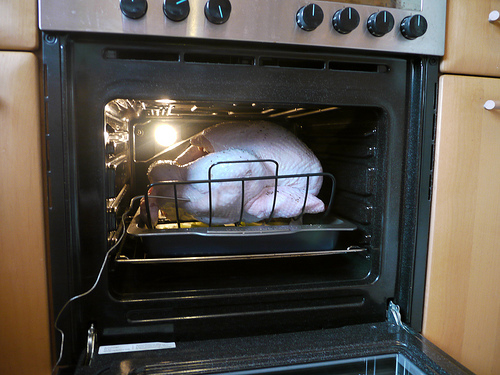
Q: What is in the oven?
A: A turkey.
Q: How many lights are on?
A: 1.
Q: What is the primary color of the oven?
A: Black.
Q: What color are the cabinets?
A: Brown.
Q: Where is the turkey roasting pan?
A: Oven.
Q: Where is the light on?
A: Oven.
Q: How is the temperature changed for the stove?
A: The controls.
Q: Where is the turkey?
A: Rack in pan.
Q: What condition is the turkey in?
A: Raw.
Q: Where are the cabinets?
A: Beside stove.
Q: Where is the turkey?
A: Oven.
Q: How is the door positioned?
A: Open.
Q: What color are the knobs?
A: Black.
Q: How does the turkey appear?
A: Uncooked.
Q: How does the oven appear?
A: Opened.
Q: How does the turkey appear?
A: Raw.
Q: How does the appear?
A: Opened.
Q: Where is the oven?
A: Near cabinet doors.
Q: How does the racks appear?
A: Shiny.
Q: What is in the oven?
A: A turkey.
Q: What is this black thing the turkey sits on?
A: Rack.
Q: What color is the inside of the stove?
A: Black.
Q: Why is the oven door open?
A: To place the turkey in.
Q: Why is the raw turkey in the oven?
A: To bake.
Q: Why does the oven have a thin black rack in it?
A: The turkey sits on it and the juices drain down through.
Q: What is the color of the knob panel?
A: Silver.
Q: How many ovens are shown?
A: One.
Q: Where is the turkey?
A: The oven.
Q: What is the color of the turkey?
A: White.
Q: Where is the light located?
A: The stove.